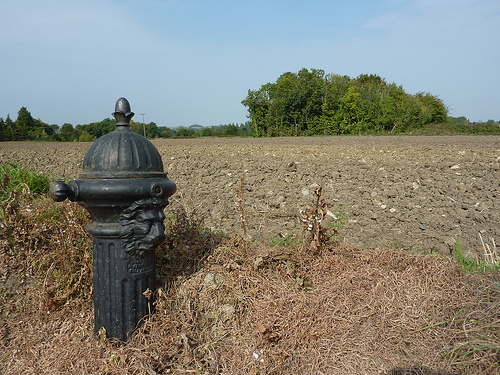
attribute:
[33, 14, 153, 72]
clouds — white 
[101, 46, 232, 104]
clouds — white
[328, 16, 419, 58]
clouds — white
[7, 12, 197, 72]
cloud — white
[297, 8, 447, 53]
cloud — white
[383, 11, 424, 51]
clouds — white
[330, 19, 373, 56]
clouds — white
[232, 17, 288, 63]
clouds — white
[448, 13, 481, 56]
clouds — white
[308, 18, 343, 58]
clouds — white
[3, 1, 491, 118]
sky — blue , clear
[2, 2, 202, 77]
clouds — white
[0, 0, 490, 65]
sky — blue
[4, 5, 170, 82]
clouds — white 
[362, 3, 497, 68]
clouds — white 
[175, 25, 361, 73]
clouds — white 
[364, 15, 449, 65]
clouds — white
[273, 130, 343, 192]
forest — tiny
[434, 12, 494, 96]
sky — blue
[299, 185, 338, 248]
weed — tiny 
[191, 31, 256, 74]
sky — blue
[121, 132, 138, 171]
line — black , raised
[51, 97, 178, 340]
pillar — dark , metal 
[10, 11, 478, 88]
clouds — white 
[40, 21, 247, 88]
sky — blue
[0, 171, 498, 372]
grass — brown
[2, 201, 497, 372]
dead grass — brown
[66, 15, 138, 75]
clouds — white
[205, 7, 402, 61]
sky — blue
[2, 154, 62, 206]
grass — brown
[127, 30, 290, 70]
clouds — white 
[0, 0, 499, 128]
sky — blue 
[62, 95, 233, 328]
hydrant — grey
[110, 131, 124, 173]
line — raised , black 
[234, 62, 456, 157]
trees — green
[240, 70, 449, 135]
trees — green, tall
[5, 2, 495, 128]
clouds — white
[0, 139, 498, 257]
dirt — light brown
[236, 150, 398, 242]
field — brown, dirty, boggy, desolate, dry, earthy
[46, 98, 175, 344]
hydrant — black, small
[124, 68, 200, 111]
clouds — white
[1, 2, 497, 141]
sky — blue , clear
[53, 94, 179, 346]
hydrant — green 